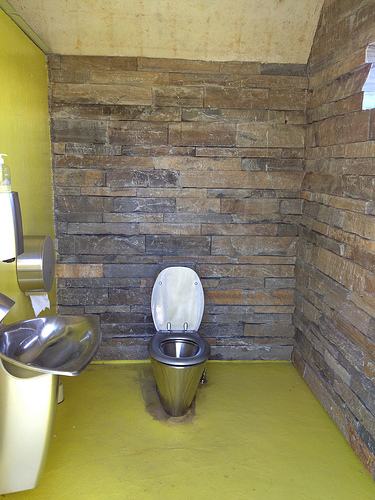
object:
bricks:
[283, 148, 305, 160]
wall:
[46, 58, 306, 362]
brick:
[106, 166, 147, 187]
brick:
[143, 234, 213, 256]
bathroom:
[1, 0, 375, 500]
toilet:
[147, 265, 210, 417]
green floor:
[0, 362, 375, 500]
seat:
[146, 329, 212, 366]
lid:
[149, 265, 205, 333]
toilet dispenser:
[15, 234, 54, 297]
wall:
[0, 9, 57, 324]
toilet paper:
[30, 295, 52, 316]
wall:
[289, 0, 374, 482]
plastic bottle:
[0, 154, 12, 185]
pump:
[0, 152, 7, 163]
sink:
[0, 312, 102, 379]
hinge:
[184, 322, 186, 330]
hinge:
[167, 322, 171, 331]